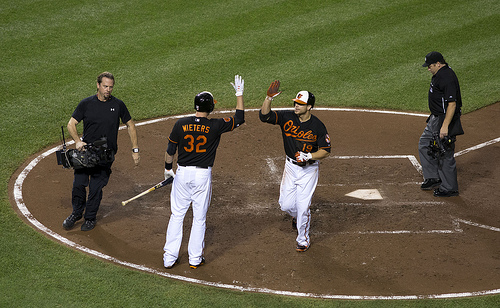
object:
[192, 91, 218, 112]
hat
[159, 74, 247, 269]
man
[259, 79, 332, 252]
man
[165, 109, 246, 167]
jersey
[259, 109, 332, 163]
jersey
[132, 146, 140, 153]
black watch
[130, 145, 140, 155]
left wrist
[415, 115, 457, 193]
pants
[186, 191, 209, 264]
leg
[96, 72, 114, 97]
head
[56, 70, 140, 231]
camera man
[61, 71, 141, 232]
person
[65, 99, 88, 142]
arm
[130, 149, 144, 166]
hand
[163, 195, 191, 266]
persons leg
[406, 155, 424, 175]
chalk line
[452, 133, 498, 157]
chalk line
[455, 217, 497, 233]
chalk line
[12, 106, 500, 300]
chalk line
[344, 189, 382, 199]
home plate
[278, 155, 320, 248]
pants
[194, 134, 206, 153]
number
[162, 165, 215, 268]
pants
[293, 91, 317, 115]
head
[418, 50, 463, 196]
umpire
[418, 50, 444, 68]
hat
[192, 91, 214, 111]
head